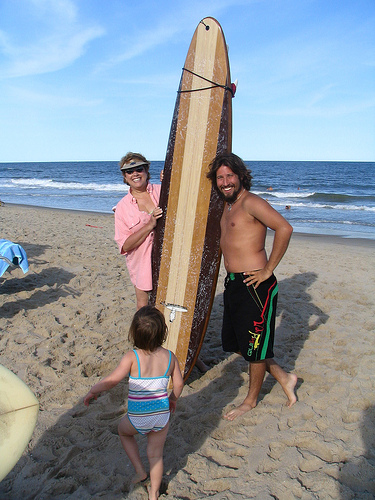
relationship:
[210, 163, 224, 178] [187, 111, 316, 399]
eye of man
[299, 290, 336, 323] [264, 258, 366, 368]
shadow on ground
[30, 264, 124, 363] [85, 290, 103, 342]
sand with footprint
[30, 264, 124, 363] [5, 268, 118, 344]
sand on beach